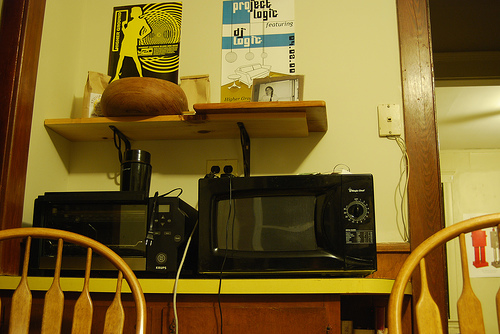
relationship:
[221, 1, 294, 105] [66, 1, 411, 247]
sign on wall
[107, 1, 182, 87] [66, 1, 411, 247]
picture on wall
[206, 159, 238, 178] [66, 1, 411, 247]
outlet on wall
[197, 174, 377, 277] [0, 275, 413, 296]
microwave on counter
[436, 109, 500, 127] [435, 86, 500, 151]
shadow on ceiling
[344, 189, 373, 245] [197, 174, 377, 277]
writing on microwave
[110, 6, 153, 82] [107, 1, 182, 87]
female figure on picture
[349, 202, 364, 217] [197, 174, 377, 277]
dial on microwave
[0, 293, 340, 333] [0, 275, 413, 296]
cabinets under counter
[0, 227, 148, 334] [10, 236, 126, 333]
chair has slats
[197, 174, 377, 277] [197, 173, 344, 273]
microwave has a door